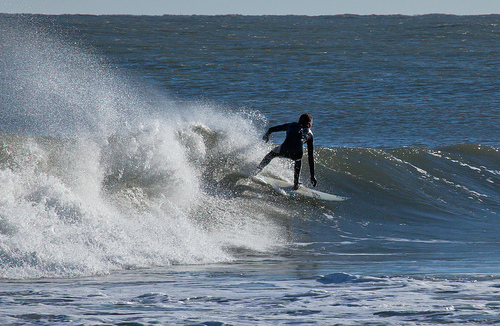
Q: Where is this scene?
A: Ocean.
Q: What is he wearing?
A: Wetsuit.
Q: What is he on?
A: Surfboard.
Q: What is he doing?
A: Surfing.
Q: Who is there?
A: Surfer.